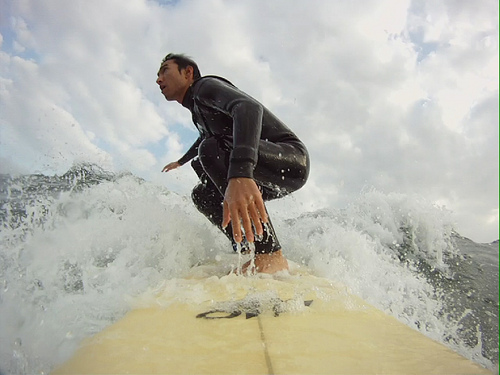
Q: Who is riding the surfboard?
A: Man in wetsuit.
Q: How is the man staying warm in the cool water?
A: Wetsuit.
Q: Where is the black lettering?
A: On the surfboard.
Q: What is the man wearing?
A: A wetsuit.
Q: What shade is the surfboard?
A: Yellow.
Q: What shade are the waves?
A: White and grey.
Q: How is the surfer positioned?
A: Crouching.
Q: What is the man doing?
A: Surfing.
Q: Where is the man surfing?
A: The ocean.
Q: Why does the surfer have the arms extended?
A: For balance.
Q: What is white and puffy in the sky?
A: Cloudsl.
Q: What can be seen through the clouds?
A: Blue sky.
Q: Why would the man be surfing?
A: For fun.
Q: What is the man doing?
A: Surfing.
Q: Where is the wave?
A: In the ocean.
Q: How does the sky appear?
A: Very cloudy.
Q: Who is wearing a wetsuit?
A: Surfer.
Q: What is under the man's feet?
A: Surfboard.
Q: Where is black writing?
A: On the surfboard.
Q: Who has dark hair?
A: The surfer.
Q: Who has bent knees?
A: Man surfing.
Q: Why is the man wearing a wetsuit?
A: To surf.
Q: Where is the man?
A: In water.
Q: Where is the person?
A: Ocean.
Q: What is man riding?
A: Wave.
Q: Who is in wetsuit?
A: A man.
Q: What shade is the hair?
A: Dark.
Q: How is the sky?
A: Cloudy.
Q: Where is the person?
A: On surfboard.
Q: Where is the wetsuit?
A: On man.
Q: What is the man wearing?
A: A wetsuit.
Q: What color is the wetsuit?
A: Black.